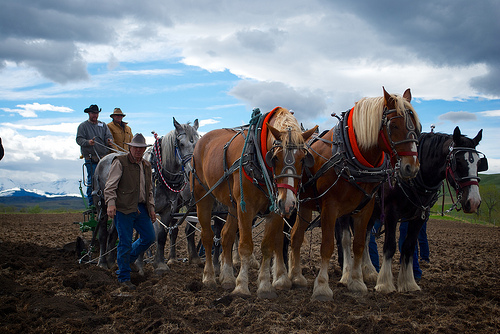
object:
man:
[74, 104, 118, 212]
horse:
[150, 116, 200, 274]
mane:
[352, 95, 405, 149]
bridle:
[240, 105, 310, 218]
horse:
[188, 105, 313, 302]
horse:
[298, 90, 417, 295]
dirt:
[1, 213, 500, 330]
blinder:
[448, 157, 489, 169]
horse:
[373, 124, 486, 295]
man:
[101, 132, 160, 289]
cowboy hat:
[125, 133, 155, 149]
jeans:
[112, 201, 158, 286]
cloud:
[0, 0, 500, 85]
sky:
[0, 30, 498, 84]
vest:
[110, 153, 152, 216]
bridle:
[331, 109, 405, 191]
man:
[105, 106, 135, 153]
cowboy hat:
[108, 105, 128, 117]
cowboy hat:
[81, 102, 102, 114]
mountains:
[0, 177, 77, 207]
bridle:
[153, 135, 190, 193]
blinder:
[265, 150, 317, 170]